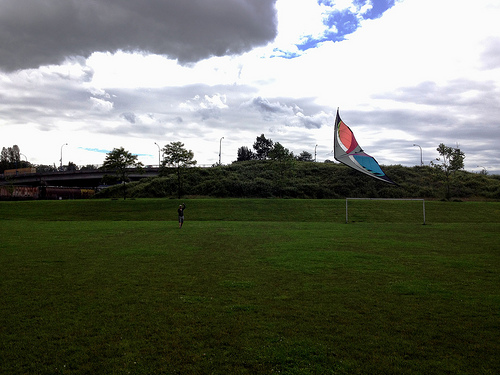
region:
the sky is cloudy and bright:
[30, 0, 485, 250]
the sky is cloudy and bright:
[142, 45, 415, 238]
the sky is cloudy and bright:
[82, 16, 385, 183]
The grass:
[271, 305, 345, 373]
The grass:
[306, 326, 334, 364]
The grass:
[268, 293, 320, 362]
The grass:
[291, 311, 325, 368]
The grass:
[261, 296, 290, 371]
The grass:
[292, 351, 313, 373]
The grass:
[304, 292, 334, 339]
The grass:
[301, 326, 321, 368]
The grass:
[313, 281, 330, 323]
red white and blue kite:
[335, 107, 387, 188]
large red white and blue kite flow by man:
[334, 106, 386, 193]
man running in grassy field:
[171, 192, 189, 228]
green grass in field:
[7, 238, 245, 352]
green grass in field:
[220, 210, 459, 340]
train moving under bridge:
[8, 183, 100, 194]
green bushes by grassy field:
[206, 165, 334, 194]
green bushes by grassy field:
[392, 169, 481, 194]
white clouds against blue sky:
[5, 4, 280, 126]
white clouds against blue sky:
[235, 5, 480, 97]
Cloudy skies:
[3, 5, 280, 71]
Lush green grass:
[182, 275, 425, 328]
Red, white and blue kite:
[325, 110, 400, 185]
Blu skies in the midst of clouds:
[310, 10, 430, 60]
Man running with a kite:
[170, 195, 190, 231]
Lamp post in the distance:
[212, 126, 227, 168]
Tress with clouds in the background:
[430, 127, 470, 183]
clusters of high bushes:
[170, 155, 350, 200]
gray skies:
[97, 72, 337, 134]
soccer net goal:
[338, 186, 441, 226]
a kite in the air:
[314, 107, 431, 210]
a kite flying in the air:
[297, 96, 389, 227]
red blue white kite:
[310, 102, 403, 201]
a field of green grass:
[230, 225, 389, 349]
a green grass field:
[203, 235, 383, 360]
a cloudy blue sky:
[154, 12, 344, 127]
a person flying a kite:
[139, 85, 436, 264]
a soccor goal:
[311, 178, 451, 245]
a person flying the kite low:
[130, 75, 439, 239]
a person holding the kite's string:
[54, 59, 454, 248]